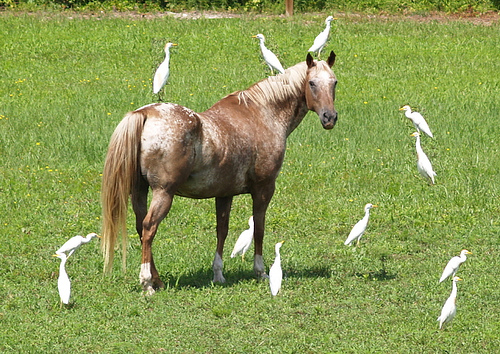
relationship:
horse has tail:
[99, 51, 338, 293] [98, 111, 141, 275]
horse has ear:
[99, 51, 338, 293] [305, 52, 316, 69]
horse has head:
[99, 51, 338, 293] [305, 54, 339, 130]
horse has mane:
[99, 51, 338, 293] [247, 60, 317, 108]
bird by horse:
[268, 242, 287, 298] [99, 51, 338, 293]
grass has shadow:
[157, 261, 394, 295] [163, 264, 329, 280]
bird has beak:
[251, 30, 287, 74] [252, 33, 258, 39]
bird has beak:
[53, 252, 75, 309] [52, 252, 60, 257]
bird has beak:
[412, 130, 439, 187] [408, 131, 416, 139]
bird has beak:
[342, 202, 379, 248] [372, 203, 379, 212]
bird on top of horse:
[150, 40, 179, 104] [99, 51, 338, 293]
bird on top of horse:
[251, 30, 287, 74] [99, 51, 338, 293]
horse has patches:
[99, 51, 338, 293] [154, 118, 177, 154]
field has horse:
[2, 0, 499, 352] [99, 51, 338, 293]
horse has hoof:
[99, 51, 338, 293] [251, 268, 269, 279]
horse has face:
[99, 51, 338, 293] [300, 51, 341, 132]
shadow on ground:
[360, 252, 398, 285] [345, 250, 417, 300]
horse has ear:
[99, 51, 338, 293] [327, 51, 337, 67]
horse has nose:
[99, 51, 338, 293] [323, 110, 340, 122]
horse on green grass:
[99, 51, 338, 293] [354, 107, 383, 143]